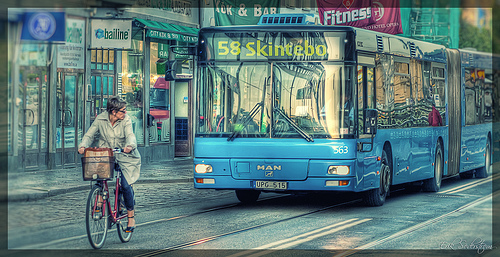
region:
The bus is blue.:
[185, 29, 457, 179]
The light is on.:
[313, 158, 354, 194]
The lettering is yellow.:
[200, 23, 351, 76]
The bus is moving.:
[185, 21, 490, 218]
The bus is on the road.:
[141, 19, 478, 254]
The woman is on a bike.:
[57, 103, 179, 231]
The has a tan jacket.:
[73, 62, 157, 230]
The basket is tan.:
[65, 141, 132, 185]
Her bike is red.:
[66, 92, 155, 250]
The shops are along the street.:
[18, 10, 202, 172]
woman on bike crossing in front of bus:
[53, 29, 393, 237]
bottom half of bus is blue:
[192, 136, 488, 178]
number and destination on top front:
[190, 27, 341, 63]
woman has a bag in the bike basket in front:
[75, 145, 120, 180]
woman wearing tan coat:
[80, 117, 150, 183]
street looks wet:
[142, 200, 424, 240]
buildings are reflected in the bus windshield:
[207, 60, 480, 127]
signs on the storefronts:
[82, 5, 458, 40]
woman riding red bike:
[67, 176, 139, 242]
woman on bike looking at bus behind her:
[82, 82, 243, 238]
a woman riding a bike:
[73, 70, 138, 255]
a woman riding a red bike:
[61, 95, 132, 255]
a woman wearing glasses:
[77, 86, 133, 138]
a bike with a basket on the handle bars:
[46, 142, 134, 202]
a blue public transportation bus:
[126, 11, 496, 234]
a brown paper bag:
[77, 142, 114, 195]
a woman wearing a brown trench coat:
[91, 85, 143, 202]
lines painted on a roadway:
[240, 164, 481, 255]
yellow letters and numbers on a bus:
[173, 23, 369, 69]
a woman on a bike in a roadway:
[37, 16, 398, 244]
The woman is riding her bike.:
[75, 91, 157, 237]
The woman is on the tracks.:
[29, 74, 239, 255]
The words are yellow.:
[190, 24, 350, 69]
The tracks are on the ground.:
[136, 202, 326, 255]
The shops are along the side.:
[20, 9, 203, 175]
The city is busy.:
[9, 19, 478, 244]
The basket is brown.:
[71, 141, 124, 198]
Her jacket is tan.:
[79, 98, 146, 198]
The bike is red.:
[61, 102, 143, 255]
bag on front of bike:
[83, 142, 113, 189]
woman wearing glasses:
[87, 87, 132, 121]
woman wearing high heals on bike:
[121, 208, 151, 230]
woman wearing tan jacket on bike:
[76, 111, 143, 185]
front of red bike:
[73, 185, 115, 251]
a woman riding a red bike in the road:
[66, 87, 149, 247]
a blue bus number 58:
[187, 25, 497, 194]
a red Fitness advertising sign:
[318, 3, 416, 31]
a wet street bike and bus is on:
[13, 192, 489, 247]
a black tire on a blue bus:
[362, 140, 412, 205]